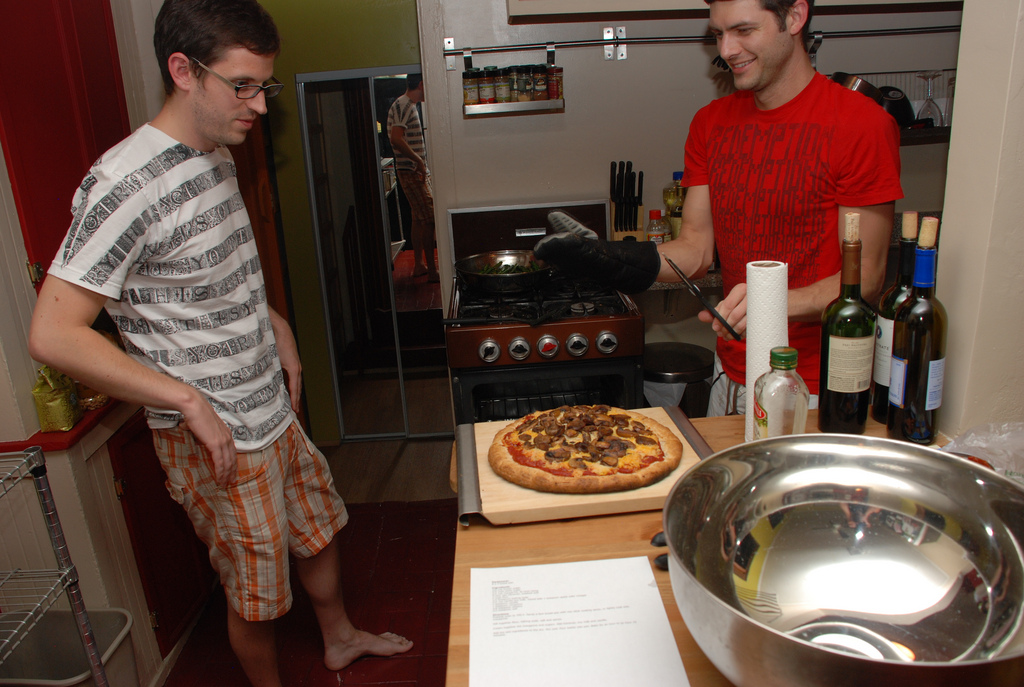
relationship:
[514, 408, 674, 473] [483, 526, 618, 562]
pizza on table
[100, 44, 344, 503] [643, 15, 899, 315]
guy near man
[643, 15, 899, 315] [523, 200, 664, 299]
man with mitt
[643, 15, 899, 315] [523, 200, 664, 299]
man wearing mitt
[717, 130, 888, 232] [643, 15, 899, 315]
shirt on man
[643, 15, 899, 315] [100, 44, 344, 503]
man with guy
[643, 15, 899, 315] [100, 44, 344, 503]
man next to guy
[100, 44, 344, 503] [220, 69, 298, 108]
guy wearing glasses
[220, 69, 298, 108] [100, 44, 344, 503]
glasses on guy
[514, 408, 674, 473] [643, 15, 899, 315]
pizza near man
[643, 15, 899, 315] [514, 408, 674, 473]
man cooking pizza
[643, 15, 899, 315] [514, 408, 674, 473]
man near pizza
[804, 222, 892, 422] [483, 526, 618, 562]
bottle on table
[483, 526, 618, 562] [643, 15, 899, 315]
table near man